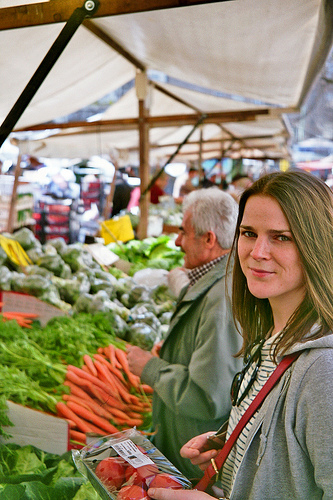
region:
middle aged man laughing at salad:
[113, 177, 242, 483]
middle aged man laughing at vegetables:
[119, 185, 252, 482]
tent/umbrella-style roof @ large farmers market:
[0, 48, 331, 165]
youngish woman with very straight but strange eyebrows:
[235, 223, 293, 238]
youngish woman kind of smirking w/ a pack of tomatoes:
[72, 162, 332, 498]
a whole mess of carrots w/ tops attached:
[0, 299, 161, 460]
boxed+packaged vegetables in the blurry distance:
[0, 165, 114, 255]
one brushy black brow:
[176, 223, 184, 233]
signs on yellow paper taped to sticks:
[0, 208, 138, 283]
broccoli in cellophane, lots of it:
[0, 237, 175, 354]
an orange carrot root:
[53, 399, 89, 432]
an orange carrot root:
[62, 398, 113, 431]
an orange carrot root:
[62, 393, 92, 411]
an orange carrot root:
[61, 378, 92, 401]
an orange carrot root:
[65, 362, 117, 399]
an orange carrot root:
[81, 351, 96, 375]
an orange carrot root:
[90, 356, 116, 390]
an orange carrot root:
[86, 348, 125, 384]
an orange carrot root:
[116, 347, 136, 388]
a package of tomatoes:
[80, 429, 190, 497]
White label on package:
[108, 437, 153, 471]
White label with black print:
[108, 436, 154, 469]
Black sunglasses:
[228, 336, 266, 406]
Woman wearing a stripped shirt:
[147, 170, 332, 498]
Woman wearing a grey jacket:
[146, 171, 332, 499]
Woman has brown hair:
[146, 171, 332, 498]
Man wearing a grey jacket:
[123, 188, 250, 481]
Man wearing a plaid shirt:
[124, 185, 247, 485]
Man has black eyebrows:
[122, 184, 245, 478]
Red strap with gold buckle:
[163, 348, 304, 491]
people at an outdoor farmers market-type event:
[2, 43, 330, 498]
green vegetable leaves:
[0, 444, 83, 499]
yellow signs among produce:
[0, 215, 134, 278]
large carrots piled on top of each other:
[1, 311, 151, 429]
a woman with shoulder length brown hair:
[223, 170, 332, 367]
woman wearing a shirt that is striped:
[218, 325, 277, 497]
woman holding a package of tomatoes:
[76, 427, 213, 498]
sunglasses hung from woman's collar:
[229, 330, 275, 408]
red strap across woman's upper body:
[193, 352, 294, 491]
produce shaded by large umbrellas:
[0, 0, 330, 499]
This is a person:
[231, 157, 327, 495]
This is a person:
[116, 178, 240, 495]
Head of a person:
[229, 161, 328, 321]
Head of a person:
[168, 169, 246, 286]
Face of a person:
[230, 189, 298, 303]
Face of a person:
[171, 199, 193, 270]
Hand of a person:
[112, 295, 248, 427]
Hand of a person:
[176, 420, 236, 476]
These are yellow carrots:
[14, 313, 157, 446]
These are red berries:
[82, 427, 199, 495]